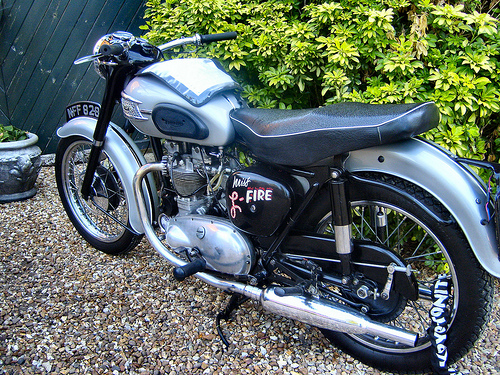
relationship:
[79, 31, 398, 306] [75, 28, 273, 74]
motorcycle has handlebar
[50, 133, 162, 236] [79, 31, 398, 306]
wheel on motorcycle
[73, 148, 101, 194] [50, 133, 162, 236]
spokes on wheel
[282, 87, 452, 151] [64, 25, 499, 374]
seat on motorcycle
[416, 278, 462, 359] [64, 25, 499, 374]
words on motorcycle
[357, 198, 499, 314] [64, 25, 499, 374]
tire on motorcycle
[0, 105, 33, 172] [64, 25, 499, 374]
flower by motorcycle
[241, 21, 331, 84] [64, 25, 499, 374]
leaves by motorcycle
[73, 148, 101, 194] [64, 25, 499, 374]
spokes of motorcycle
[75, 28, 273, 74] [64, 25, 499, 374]
handlebar on motorcycle